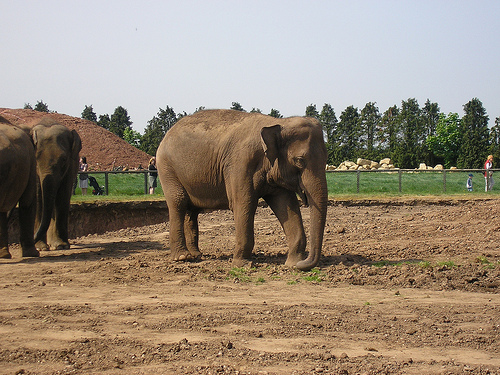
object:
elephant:
[154, 108, 329, 271]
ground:
[0, 170, 499, 374]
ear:
[260, 122, 281, 169]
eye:
[295, 155, 306, 166]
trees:
[350, 97, 388, 151]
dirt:
[0, 196, 499, 374]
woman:
[148, 157, 158, 194]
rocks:
[325, 156, 398, 173]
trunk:
[298, 177, 328, 270]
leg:
[225, 159, 255, 265]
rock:
[224, 340, 235, 349]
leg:
[153, 156, 194, 260]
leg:
[183, 207, 203, 259]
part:
[406, 207, 483, 237]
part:
[296, 258, 316, 270]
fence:
[71, 169, 498, 194]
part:
[399, 169, 446, 195]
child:
[465, 173, 475, 192]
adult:
[481, 153, 493, 196]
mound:
[0, 200, 169, 242]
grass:
[403, 170, 443, 193]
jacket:
[482, 160, 494, 177]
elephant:
[26, 120, 83, 252]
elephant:
[1, 116, 42, 258]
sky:
[0, 2, 151, 97]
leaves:
[461, 103, 488, 167]